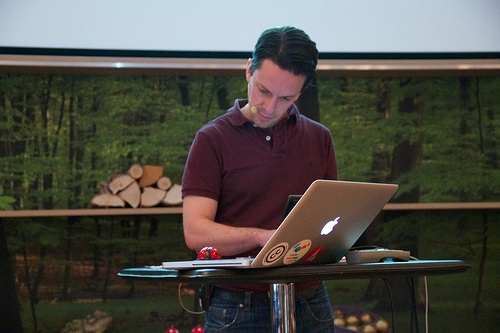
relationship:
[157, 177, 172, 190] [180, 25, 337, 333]
fire wood behind man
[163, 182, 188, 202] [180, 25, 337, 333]
fire wood behind man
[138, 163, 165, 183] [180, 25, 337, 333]
fire wood behind man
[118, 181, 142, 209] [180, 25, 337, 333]
fire wood behind man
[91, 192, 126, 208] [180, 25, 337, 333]
fire wood behind man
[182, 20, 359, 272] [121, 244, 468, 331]
man standing at podium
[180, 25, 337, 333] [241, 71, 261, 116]
man has a microphone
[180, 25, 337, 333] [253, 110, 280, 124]
man has a mouth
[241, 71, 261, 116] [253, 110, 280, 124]
microphone by h mouth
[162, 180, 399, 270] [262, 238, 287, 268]
computer has sticker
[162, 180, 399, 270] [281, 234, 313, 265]
computer has sticker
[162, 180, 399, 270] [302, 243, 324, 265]
computer has sticker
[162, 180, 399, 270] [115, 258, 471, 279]
computer over podium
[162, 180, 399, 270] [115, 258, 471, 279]
computer it podium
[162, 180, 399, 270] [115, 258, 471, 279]
computer on it podium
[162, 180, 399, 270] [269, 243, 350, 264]
computer has stickers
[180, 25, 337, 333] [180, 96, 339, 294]
man wearing polo shirt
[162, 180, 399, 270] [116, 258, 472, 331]
computer on table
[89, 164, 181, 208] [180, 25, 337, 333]
wood behind man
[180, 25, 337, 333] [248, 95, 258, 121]
man wearing microphone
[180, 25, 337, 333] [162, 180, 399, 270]
man had computer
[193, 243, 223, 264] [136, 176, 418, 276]
ladybug on computer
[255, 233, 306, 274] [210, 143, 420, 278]
stickers on back of computer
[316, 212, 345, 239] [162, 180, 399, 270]
apple logo on computer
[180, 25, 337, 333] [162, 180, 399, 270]
man using computer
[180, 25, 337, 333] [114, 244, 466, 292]
man standing at table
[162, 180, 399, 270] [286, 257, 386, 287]
computer on table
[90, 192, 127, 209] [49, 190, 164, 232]
fire wood on shelf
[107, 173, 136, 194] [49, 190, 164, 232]
fire wood on shelf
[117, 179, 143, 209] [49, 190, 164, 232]
fire wood on shelf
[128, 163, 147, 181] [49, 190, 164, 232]
fire wood on shelf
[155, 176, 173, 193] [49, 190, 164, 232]
fire wood on shelf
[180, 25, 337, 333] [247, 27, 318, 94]
man with hair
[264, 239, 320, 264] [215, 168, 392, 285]
stickers on laptop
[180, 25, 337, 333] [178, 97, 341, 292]
man wearing shirt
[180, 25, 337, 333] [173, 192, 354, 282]
man using laptop